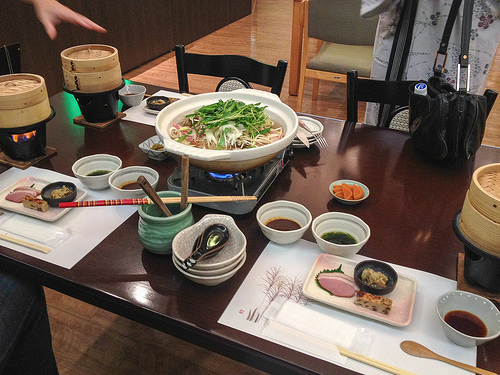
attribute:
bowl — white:
[434, 290, 497, 347]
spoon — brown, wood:
[398, 337, 498, 373]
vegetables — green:
[180, 95, 266, 148]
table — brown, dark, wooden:
[6, 67, 498, 370]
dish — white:
[166, 207, 242, 287]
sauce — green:
[324, 231, 356, 249]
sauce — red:
[266, 214, 300, 228]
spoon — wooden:
[399, 334, 480, 372]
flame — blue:
[202, 173, 240, 187]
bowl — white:
[255, 189, 309, 247]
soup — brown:
[446, 302, 487, 331]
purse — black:
[412, 9, 493, 176]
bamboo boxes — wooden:
[2, 40, 120, 134]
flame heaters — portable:
[10, 87, 126, 165]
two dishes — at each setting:
[66, 152, 161, 200]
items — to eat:
[6, 180, 84, 215]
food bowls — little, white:
[251, 198, 371, 254]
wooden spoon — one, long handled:
[397, 336, 476, 367]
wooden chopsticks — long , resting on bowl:
[54, 194, 259, 201]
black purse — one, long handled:
[408, 1, 484, 164]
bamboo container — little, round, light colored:
[58, 42, 125, 93]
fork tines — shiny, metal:
[310, 129, 329, 151]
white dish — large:
[152, 87, 302, 164]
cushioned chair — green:
[297, 2, 415, 102]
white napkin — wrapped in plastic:
[277, 297, 372, 351]